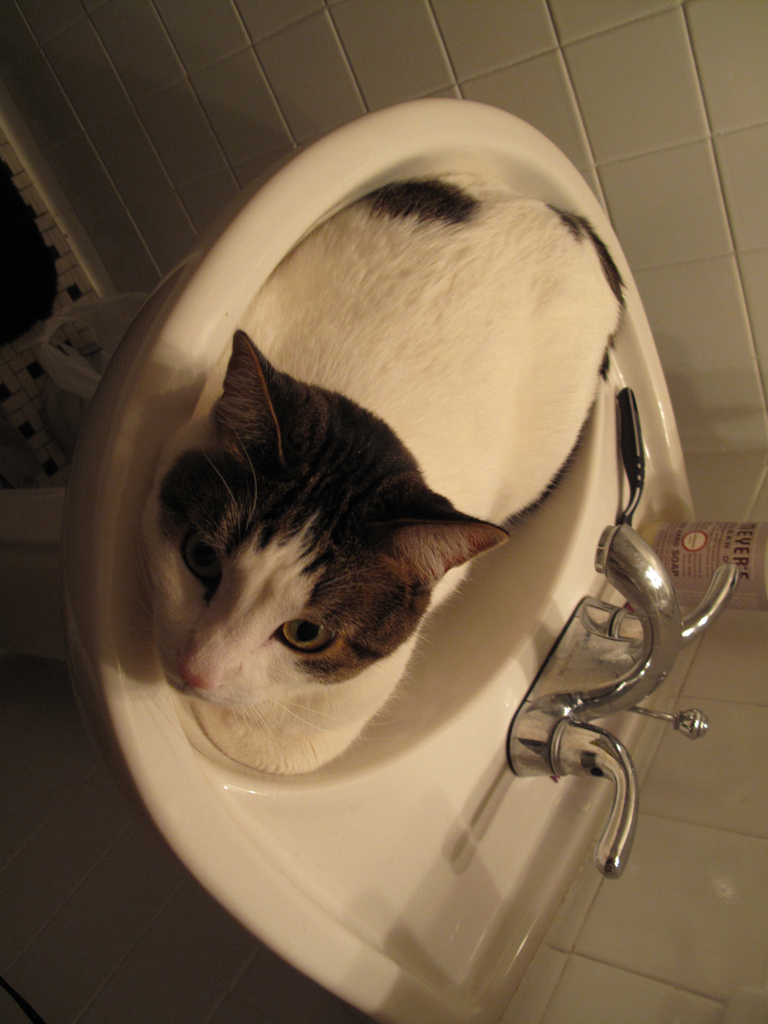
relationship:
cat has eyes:
[133, 173, 627, 770] [169, 529, 353, 665]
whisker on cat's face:
[133, 491, 233, 647] [144, 389, 456, 816]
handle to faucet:
[582, 740, 669, 883] [532, 470, 720, 807]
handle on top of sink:
[565, 721, 641, 877] [328, 230, 716, 873]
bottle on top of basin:
[638, 518, 767, 612] [402, 305, 741, 874]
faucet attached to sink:
[508, 465, 750, 921] [98, 206, 741, 883]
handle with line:
[609, 381, 688, 519] [624, 395, 650, 470]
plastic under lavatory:
[32, 297, 164, 456] [148, 171, 661, 962]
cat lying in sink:
[133, 173, 627, 770] [4, 100, 703, 1013]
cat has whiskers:
[133, 173, 627, 770] [181, 385, 263, 559]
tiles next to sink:
[77, 78, 248, 207] [4, 100, 703, 1013]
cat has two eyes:
[133, 173, 627, 770] [174, 519, 340, 657]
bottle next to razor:
[638, 516, 742, 594] [616, 382, 650, 534]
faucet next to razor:
[508, 520, 743, 877] [606, 378, 647, 526]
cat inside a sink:
[133, 173, 627, 770] [4, 100, 703, 1013]